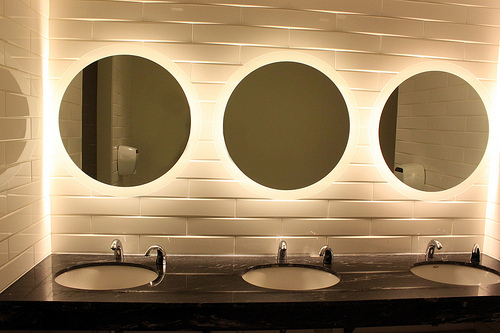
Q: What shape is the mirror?
A: Circular.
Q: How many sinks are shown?
A: Three.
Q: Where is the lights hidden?
A: Behind the mirrors.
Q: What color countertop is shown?
A: Black.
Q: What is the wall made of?
A: Subway tile.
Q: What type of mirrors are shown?
A: Circular bathroom mirror.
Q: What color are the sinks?
A: White.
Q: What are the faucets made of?
A: Metal.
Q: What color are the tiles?
A: White.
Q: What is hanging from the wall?
A: Mirrors.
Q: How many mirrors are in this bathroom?
A: 3.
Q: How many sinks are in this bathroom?
A: 3.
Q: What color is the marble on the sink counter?
A: Black.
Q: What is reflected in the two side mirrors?
A: Hand dryers.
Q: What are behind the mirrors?
A: Lights.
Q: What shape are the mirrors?
A: Circles.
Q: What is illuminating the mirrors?
A: Lights.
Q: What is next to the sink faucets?
A: Soap dispensers.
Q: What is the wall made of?
A: Brick.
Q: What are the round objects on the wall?
A: Mirrors.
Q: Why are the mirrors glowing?
A: Lights.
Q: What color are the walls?
A: White.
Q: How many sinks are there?
A: 3.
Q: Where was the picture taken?
A: Bathroom.